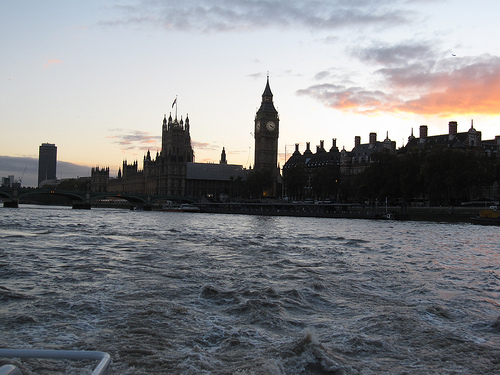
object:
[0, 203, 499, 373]
body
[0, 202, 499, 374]
water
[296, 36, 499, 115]
cloud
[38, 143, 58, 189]
building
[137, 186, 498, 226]
shore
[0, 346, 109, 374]
pipe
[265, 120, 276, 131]
clock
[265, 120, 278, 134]
face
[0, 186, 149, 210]
bridge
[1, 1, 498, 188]
sky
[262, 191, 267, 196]
light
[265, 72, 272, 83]
tip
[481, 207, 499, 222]
bowl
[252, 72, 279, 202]
big ben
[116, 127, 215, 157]
cloud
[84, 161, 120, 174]
sun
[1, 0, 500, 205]
other side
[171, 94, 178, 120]
flag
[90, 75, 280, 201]
building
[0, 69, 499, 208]
town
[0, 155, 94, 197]
mountain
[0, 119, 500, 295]
distance